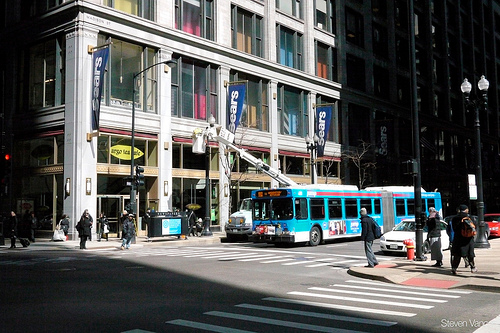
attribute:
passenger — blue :
[355, 203, 382, 271]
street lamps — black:
[458, 73, 492, 248]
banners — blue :
[222, 74, 323, 151]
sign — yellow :
[107, 138, 148, 162]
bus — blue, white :
[246, 184, 448, 246]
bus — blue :
[248, 187, 452, 249]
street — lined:
[125, 195, 407, 307]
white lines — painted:
[284, 282, 402, 327]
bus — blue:
[256, 170, 463, 242]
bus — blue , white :
[234, 172, 443, 261]